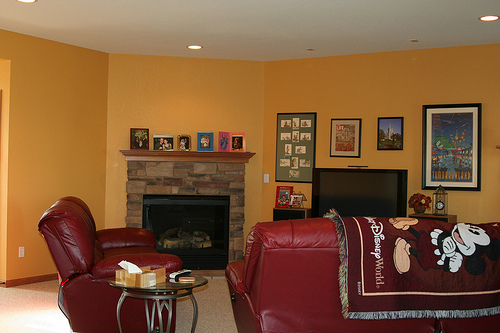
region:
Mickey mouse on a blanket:
[386, 215, 498, 275]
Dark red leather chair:
[38, 194, 183, 330]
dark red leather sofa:
[226, 218, 497, 330]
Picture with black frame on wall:
[421, 103, 483, 191]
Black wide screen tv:
[310, 165, 408, 217]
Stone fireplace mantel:
[118, 147, 256, 271]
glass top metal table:
[110, 269, 207, 330]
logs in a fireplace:
[155, 223, 212, 248]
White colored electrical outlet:
[18, 245, 25, 257]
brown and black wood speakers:
[271, 206, 456, 223]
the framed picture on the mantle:
[130, 126, 150, 147]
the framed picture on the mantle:
[152, 135, 175, 150]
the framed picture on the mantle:
[178, 131, 190, 151]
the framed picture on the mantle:
[197, 131, 214, 153]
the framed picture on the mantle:
[217, 130, 229, 155]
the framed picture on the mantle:
[232, 134, 246, 151]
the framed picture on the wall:
[275, 109, 315, 179]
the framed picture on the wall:
[330, 116, 358, 158]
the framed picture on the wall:
[377, 114, 402, 151]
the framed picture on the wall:
[421, 103, 480, 190]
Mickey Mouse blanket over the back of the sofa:
[337, 214, 498, 320]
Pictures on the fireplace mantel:
[125, 124, 248, 155]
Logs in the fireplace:
[158, 220, 212, 256]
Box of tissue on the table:
[115, 259, 158, 287]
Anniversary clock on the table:
[431, 182, 450, 222]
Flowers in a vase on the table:
[409, 189, 433, 218]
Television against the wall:
[315, 163, 408, 222]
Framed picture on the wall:
[421, 102, 481, 192]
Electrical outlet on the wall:
[16, 240, 26, 263]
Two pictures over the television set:
[328, 114, 404, 161]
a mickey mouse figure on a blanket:
[368, 202, 493, 291]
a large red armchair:
[24, 183, 173, 321]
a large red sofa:
[222, 216, 459, 331]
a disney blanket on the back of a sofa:
[306, 198, 498, 323]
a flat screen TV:
[305, 157, 411, 228]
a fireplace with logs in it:
[121, 183, 236, 280]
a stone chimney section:
[110, 146, 260, 292]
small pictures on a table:
[272, 178, 306, 213]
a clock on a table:
[434, 190, 451, 220]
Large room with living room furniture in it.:
[0, 0, 497, 331]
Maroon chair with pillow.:
[38, 193, 185, 331]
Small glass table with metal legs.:
[108, 260, 218, 331]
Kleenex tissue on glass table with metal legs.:
[111, 260, 213, 331]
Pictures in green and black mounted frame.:
[271, 110, 319, 187]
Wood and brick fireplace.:
[115, 122, 257, 278]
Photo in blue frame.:
[195, 126, 217, 151]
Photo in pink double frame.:
[215, 127, 245, 152]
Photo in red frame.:
[275, 183, 297, 210]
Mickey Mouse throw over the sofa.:
[338, 212, 498, 317]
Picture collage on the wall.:
[272, 109, 319, 186]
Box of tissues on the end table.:
[116, 258, 167, 288]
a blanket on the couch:
[283, 195, 461, 332]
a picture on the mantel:
[176, 134, 195, 154]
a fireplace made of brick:
[106, 140, 354, 324]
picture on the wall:
[249, 95, 359, 205]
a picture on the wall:
[381, 115, 421, 162]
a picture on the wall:
[437, 98, 482, 194]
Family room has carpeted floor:
[1, 3, 495, 331]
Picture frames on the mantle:
[118, 123, 258, 165]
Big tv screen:
[308, 165, 410, 219]